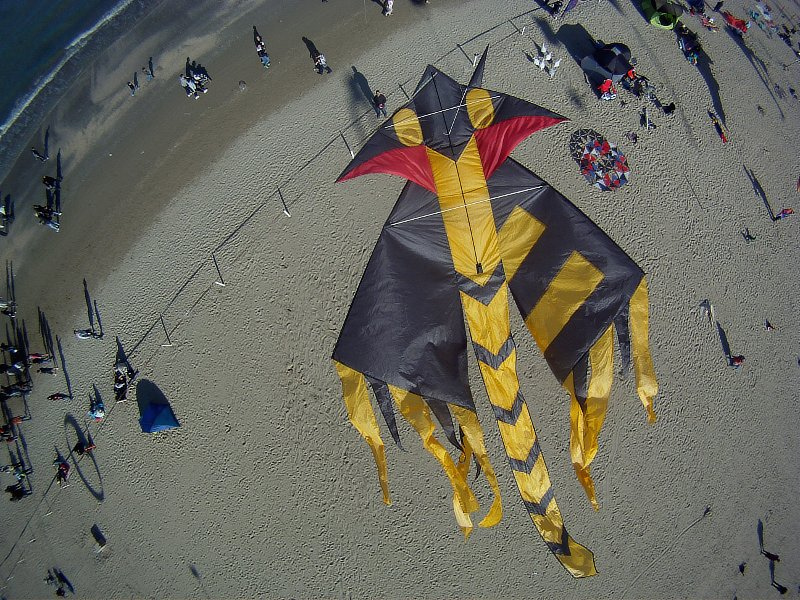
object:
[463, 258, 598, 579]
stripes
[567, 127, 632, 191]
umbrellas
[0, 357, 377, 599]
sand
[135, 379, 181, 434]
blue umbrella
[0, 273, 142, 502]
people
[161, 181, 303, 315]
poles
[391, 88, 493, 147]
golden eyes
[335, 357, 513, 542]
streamers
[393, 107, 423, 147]
yellow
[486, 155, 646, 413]
grey wing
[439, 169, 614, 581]
yellow tail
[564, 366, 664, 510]
yellow frill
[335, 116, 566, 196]
red patch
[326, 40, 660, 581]
kite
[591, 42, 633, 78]
umbrella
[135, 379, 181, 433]
umbrella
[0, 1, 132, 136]
water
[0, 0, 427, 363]
sand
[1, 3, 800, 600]
sand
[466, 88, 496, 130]
eye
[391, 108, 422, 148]
eye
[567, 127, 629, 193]
kite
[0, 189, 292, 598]
beach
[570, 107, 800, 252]
sand